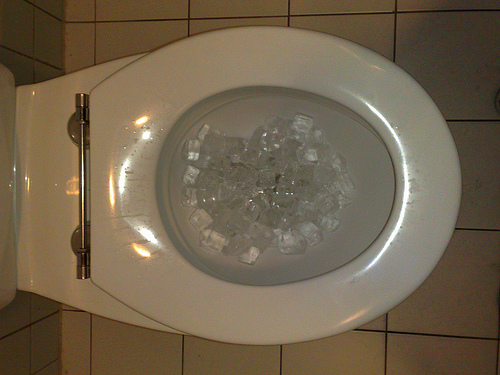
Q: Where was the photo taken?
A: It was taken at the bathroom.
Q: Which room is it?
A: It is a bathroom.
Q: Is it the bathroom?
A: Yes, it is the bathroom.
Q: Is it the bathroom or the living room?
A: It is the bathroom.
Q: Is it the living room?
A: No, it is the bathroom.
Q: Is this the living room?
A: No, it is the bathroom.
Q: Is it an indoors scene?
A: Yes, it is indoors.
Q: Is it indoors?
A: Yes, it is indoors.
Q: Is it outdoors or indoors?
A: It is indoors.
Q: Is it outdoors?
A: No, it is indoors.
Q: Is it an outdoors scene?
A: No, it is indoors.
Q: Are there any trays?
A: No, there are no trays.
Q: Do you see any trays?
A: No, there are no trays.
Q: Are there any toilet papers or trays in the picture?
A: No, there are no trays or toilet papers.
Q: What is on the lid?
A: The water is on the lid.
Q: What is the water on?
A: The water is on the lid.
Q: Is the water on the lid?
A: Yes, the water is on the lid.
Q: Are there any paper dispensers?
A: No, there are no paper dispensers.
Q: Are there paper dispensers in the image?
A: No, there are no paper dispensers.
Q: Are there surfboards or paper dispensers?
A: No, there are no paper dispensers or surfboards.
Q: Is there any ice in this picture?
A: Yes, there is ice.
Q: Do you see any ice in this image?
A: Yes, there is ice.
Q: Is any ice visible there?
A: Yes, there is ice.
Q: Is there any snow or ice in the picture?
A: Yes, there is ice.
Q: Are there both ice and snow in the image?
A: No, there is ice but no snow.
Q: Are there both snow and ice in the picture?
A: No, there is ice but no snow.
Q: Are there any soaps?
A: No, there are no soaps.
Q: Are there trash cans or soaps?
A: No, there are no soaps or trash cans.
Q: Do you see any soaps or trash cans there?
A: No, there are no soaps or trash cans.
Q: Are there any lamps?
A: No, there are no lamps.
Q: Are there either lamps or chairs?
A: No, there are no lamps or chairs.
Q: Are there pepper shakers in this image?
A: No, there are no pepper shakers.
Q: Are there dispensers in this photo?
A: No, there are no dispensers.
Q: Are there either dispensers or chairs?
A: No, there are no dispensers or chairs.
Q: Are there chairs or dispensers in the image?
A: No, there are no dispensers or chairs.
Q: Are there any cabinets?
A: No, there are no cabinets.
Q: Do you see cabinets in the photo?
A: No, there are no cabinets.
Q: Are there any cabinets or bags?
A: No, there are no cabinets or bags.